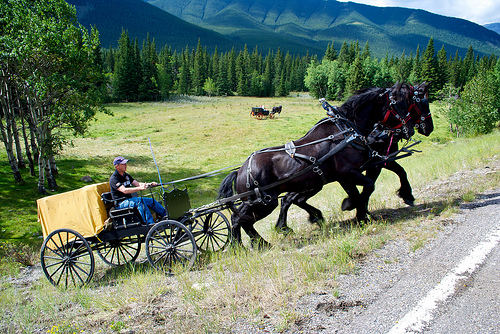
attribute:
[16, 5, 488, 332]
day — bright, sunny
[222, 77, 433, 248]
horses — BLACK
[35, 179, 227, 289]
carriage — OLD FASHIONED, FOUR, WHEELED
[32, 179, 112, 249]
box — YELLOW, COVERED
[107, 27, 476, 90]
trees — GREEN, EVERGREEN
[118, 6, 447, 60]
range — EXPANSIVE, MOUNTAIN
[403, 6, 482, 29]
sky — LIGHT, BLUE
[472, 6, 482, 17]
clouds — WHITE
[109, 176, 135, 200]
shirt — BLUE, TEE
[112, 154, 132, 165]
cap — BLUE, BASEBALL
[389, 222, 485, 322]
road — GRAY, CONCRETE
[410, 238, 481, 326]
line — WHITE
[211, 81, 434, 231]
horses — pair 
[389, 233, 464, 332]
line — road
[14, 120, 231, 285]
carriage — back wheel 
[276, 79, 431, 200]
bridle —  horse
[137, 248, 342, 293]
weeds — patch 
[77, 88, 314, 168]
field — background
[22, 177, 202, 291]
wagon — front wheel 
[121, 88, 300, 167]
field — tree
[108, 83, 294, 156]
field — tree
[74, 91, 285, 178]
field — tree